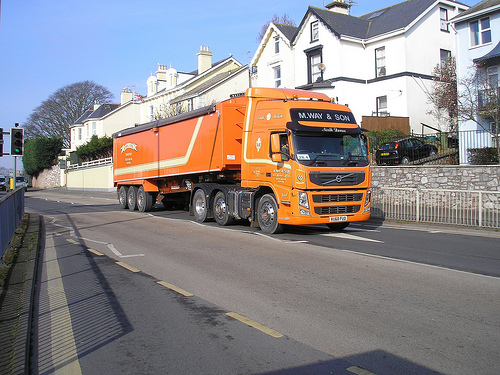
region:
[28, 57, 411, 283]
the truck is orange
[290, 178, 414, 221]
the headlights are off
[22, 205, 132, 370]
shadow on the street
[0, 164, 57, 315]
the fence is grey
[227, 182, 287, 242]
the wheel is black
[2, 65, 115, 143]
the trees are bare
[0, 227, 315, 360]
yellow lines on the street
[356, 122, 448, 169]
the car is parked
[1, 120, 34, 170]
the light is green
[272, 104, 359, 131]
the letters are white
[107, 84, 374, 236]
Orange truck on a road.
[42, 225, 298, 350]
Yellow lines on a street.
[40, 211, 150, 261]
White lines painted on a road.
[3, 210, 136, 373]
The shadow of a fence.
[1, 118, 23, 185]
Streetlight next to a fence.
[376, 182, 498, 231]
Fence in front of a brick wall.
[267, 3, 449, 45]
Roof of a white house.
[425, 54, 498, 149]
Tree in front of a house.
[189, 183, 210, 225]
Tire on an orange truck.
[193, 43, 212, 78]
Chimney on a rooftop.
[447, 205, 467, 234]
part of a rail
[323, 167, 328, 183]
part of a truck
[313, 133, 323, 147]
part of a window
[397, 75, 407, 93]
edge of a house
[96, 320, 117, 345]
part of a shadow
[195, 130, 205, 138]
side of a truck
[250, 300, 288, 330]
edge of a road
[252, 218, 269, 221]
part of a wheel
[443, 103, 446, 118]
part of a bush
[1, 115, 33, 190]
street light is green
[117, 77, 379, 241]
large orange truck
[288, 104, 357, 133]
M.WAY & SON on front of truck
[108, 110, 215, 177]
line on side of truck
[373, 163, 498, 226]
stone wall in front of homes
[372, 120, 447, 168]
car in the driveway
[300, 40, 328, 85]
black trim around the window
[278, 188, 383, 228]
front lights on the truck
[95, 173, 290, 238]
six wheels on one side of the truck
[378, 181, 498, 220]
fence along the road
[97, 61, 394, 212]
truck driving on street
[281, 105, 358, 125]
sign on a truck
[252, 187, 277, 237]
tire on a truck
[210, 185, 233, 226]
tire on a truck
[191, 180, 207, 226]
tire on a truck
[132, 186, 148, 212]
tire on a truck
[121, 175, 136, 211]
tire on a truck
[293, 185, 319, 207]
light on a truck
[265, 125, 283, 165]
mirror on a truck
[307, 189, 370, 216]
grill on a truck